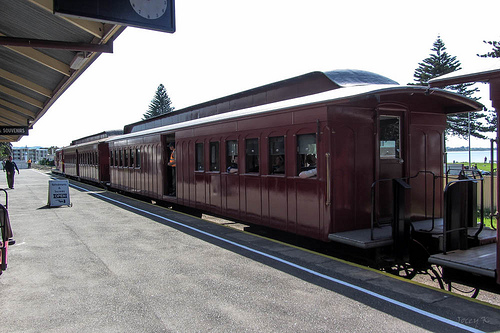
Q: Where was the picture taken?
A: At a train station.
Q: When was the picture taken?
A: Daytime.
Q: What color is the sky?
A: White.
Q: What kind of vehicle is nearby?
A: A train.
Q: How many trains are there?
A: One.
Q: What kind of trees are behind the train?
A: Pine trees.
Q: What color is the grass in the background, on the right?
A: Green.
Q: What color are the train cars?
A: Burgundy.